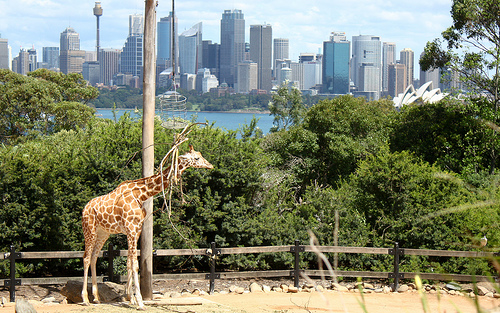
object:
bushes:
[0, 82, 500, 277]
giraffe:
[80, 145, 213, 311]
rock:
[397, 284, 409, 293]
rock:
[249, 282, 262, 292]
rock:
[199, 291, 210, 296]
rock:
[315, 285, 324, 292]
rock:
[374, 288, 384, 293]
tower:
[93, 2, 103, 62]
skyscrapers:
[218, 8, 245, 88]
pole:
[140, 0, 154, 300]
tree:
[0, 66, 97, 137]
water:
[0, 108, 304, 141]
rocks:
[229, 285, 238, 292]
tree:
[0, 121, 124, 271]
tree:
[215, 138, 263, 207]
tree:
[300, 95, 397, 188]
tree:
[420, 0, 499, 114]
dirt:
[0, 291, 500, 312]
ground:
[0, 279, 500, 313]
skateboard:
[404, 249, 500, 260]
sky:
[0, 0, 500, 77]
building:
[323, 41, 349, 95]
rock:
[40, 292, 67, 305]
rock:
[235, 287, 245, 293]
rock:
[262, 285, 271, 292]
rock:
[477, 286, 489, 296]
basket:
[159, 95, 188, 129]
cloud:
[379, 11, 446, 32]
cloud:
[291, 4, 327, 19]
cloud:
[292, 25, 318, 32]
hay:
[165, 123, 190, 181]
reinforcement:
[203, 242, 220, 293]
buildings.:
[250, 25, 274, 95]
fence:
[0, 241, 500, 301]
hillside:
[0, 66, 500, 278]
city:
[0, 0, 500, 112]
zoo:
[0, 70, 500, 313]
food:
[115, 143, 175, 182]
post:
[210, 241, 216, 293]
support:
[389, 242, 405, 292]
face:
[188, 152, 214, 170]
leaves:
[420, 41, 452, 71]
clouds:
[28, 0, 80, 13]